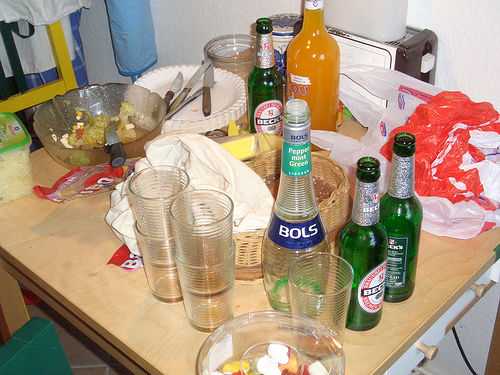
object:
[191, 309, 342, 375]
bowl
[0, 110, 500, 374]
table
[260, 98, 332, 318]
bottle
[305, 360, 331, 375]
food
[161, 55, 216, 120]
dinner ware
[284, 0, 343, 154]
drink